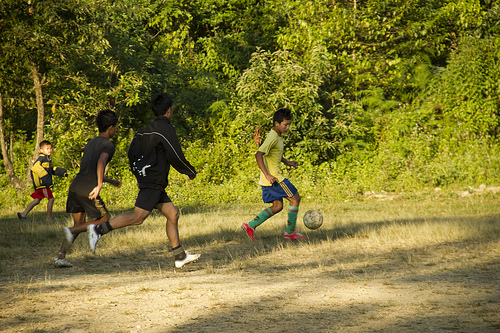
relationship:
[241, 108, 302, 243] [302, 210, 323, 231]
boy kicking ball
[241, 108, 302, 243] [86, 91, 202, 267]
boy playing with boy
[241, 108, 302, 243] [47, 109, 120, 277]
boy playing with boy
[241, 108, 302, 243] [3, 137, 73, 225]
boy playing with boy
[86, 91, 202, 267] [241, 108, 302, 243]
boy playing with boy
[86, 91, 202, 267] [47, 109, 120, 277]
boy playing with boy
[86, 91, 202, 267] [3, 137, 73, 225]
boy playing with boy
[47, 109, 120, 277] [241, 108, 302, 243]
boy playing with boy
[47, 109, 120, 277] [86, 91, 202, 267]
boy playing with boy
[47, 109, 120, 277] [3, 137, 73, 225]
boy playing with boy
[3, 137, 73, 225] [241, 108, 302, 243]
boy playing with boy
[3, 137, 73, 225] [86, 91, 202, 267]
boy playing with boy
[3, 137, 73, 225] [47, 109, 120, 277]
boy playing with boy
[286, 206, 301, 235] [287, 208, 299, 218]
knee sock with stripe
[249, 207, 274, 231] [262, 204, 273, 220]
knee sock with stripe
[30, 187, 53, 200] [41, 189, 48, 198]
red shorts with strips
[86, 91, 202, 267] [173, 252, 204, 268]
boy wearing shoes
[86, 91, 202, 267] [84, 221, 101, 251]
boy wearing tennis shoe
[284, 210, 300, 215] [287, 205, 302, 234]
stripe on knee sock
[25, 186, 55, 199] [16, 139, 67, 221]
red shorts on boy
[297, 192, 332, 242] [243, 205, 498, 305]
ball on ground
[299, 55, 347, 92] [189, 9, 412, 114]
leaves on trees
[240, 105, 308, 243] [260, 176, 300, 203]
boy wearing shorts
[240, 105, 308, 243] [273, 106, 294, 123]
boy with black hair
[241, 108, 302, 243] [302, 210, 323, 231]
boy play ball